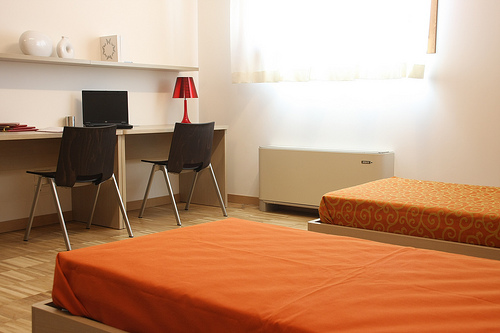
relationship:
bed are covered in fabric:
[307, 176, 500, 261] [51, 216, 498, 332]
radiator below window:
[258, 146, 394, 212] [226, 0, 442, 89]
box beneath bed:
[307, 215, 499, 266] [307, 175, 498, 263]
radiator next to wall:
[258, 146, 394, 212] [200, 2, 499, 196]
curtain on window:
[228, 1, 435, 85] [226, 0, 442, 89]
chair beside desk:
[22, 125, 135, 252] [1, 121, 236, 231]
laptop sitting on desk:
[80, 89, 134, 131] [1, 121, 236, 231]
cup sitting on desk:
[64, 115, 78, 130] [1, 121, 236, 231]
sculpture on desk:
[57, 34, 77, 62] [1, 121, 236, 231]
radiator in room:
[258, 146, 394, 212] [1, 0, 499, 329]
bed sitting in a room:
[307, 175, 498, 263] [1, 0, 499, 329]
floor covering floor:
[2, 201, 320, 332] [2, 201, 320, 332]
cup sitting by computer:
[64, 115, 78, 130] [80, 89, 134, 131]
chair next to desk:
[22, 125, 135, 252] [1, 121, 236, 231]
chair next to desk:
[138, 121, 230, 225] [1, 121, 236, 231]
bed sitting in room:
[33, 214, 498, 333] [1, 0, 499, 329]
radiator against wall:
[258, 146, 394, 212] [200, 2, 499, 196]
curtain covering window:
[228, 1, 435, 85] [226, 0, 442, 89]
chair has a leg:
[22, 125, 135, 252] [47, 177, 76, 254]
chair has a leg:
[22, 125, 135, 252] [109, 173, 140, 238]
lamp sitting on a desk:
[172, 75, 199, 131] [1, 121, 236, 231]